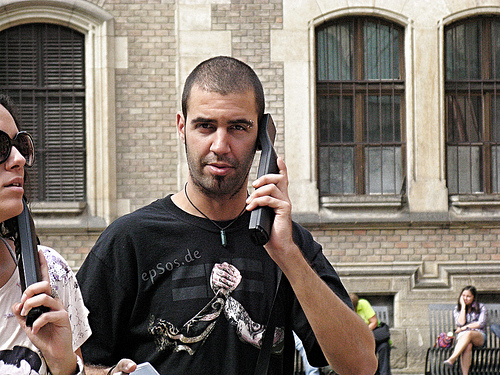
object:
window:
[307, 6, 409, 207]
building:
[1, 0, 500, 375]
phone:
[246, 111, 279, 247]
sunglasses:
[0, 128, 37, 168]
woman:
[0, 92, 93, 375]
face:
[0, 104, 35, 217]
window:
[0, 16, 99, 221]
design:
[140, 243, 286, 359]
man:
[73, 52, 379, 375]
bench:
[426, 302, 500, 374]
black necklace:
[184, 181, 252, 248]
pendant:
[219, 228, 228, 248]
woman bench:
[420, 281, 499, 375]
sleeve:
[277, 216, 359, 371]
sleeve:
[74, 218, 139, 373]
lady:
[439, 282, 494, 374]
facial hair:
[183, 129, 255, 200]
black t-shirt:
[64, 192, 355, 375]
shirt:
[354, 298, 382, 328]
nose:
[209, 138, 231, 156]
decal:
[144, 262, 291, 360]